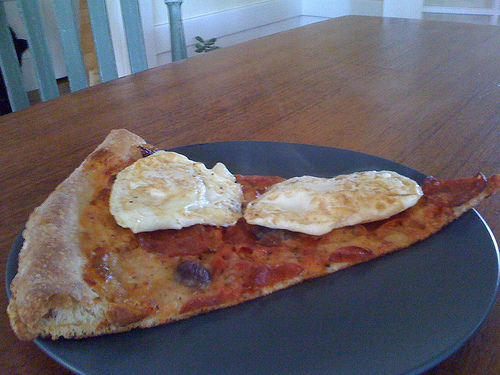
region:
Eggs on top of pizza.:
[141, 144, 293, 222]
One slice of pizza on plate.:
[28, 114, 478, 290]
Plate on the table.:
[55, 108, 465, 358]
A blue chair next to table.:
[16, 30, 206, 85]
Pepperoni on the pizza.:
[154, 223, 218, 261]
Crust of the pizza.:
[18, 196, 91, 341]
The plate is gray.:
[283, 280, 488, 374]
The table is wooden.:
[233, 45, 453, 137]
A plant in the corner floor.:
[191, 25, 233, 76]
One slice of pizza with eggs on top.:
[66, 120, 468, 282]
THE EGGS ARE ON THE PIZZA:
[100, 122, 427, 255]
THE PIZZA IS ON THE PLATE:
[18, 111, 498, 346]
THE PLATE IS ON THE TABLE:
[3, 129, 499, 373]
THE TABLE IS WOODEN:
[3, 11, 495, 370]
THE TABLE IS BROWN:
[3, 9, 498, 374]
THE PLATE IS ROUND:
[5, 129, 499, 374]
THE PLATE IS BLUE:
[3, 130, 497, 372]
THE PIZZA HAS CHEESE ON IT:
[6, 119, 498, 354]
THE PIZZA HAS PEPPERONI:
[80, 155, 490, 317]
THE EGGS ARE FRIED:
[111, 134, 422, 254]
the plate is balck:
[205, 324, 430, 353]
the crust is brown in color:
[17, 209, 66, 331]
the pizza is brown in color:
[103, 232, 321, 269]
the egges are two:
[131, 151, 415, 221]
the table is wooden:
[209, 42, 416, 110]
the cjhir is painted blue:
[11, 17, 151, 62]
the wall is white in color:
[194, 10, 323, 22]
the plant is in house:
[191, 36, 216, 51]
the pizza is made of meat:
[171, 261, 213, 290]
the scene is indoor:
[23, 6, 480, 373]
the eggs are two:
[126, 158, 439, 248]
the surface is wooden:
[288, 18, 491, 122]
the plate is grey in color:
[1, 122, 498, 369]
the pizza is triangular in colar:
[9, 145, 497, 340]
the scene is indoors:
[9, 6, 486, 373]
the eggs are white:
[264, 169, 413, 225]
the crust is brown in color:
[23, 226, 80, 335]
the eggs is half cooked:
[131, 161, 243, 231]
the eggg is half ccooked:
[262, 165, 421, 235]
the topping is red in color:
[181, 237, 313, 292]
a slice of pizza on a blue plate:
[23, 139, 451, 326]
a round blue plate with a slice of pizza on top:
[28, 132, 496, 374]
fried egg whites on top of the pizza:
[99, 138, 422, 237]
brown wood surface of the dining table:
[286, 23, 436, 138]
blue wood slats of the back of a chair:
[0, 12, 211, 81]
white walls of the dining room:
[178, 3, 273, 42]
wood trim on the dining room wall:
[168, 8, 301, 42]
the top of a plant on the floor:
[191, 21, 234, 56]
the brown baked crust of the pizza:
[9, 132, 126, 336]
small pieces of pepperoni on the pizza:
[167, 246, 360, 301]